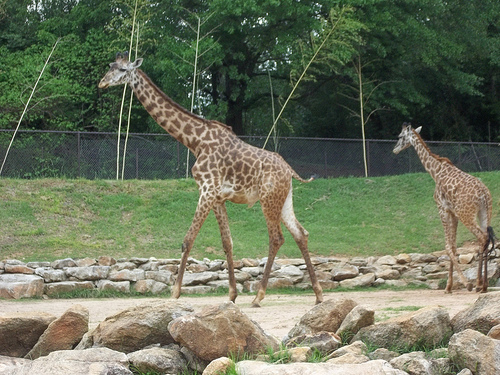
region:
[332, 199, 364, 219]
A slope covered in green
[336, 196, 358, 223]
Green grass on a slope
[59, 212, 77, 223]
A slope with dry grass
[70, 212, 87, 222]
Dry grass on a slope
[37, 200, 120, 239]
A slopy surface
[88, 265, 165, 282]
Stones arranged to make a wall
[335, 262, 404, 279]
A low wall of stones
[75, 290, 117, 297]
grass growing next to blocks of stone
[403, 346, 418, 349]
Growth of grass betwen rocks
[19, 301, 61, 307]
A path between rocks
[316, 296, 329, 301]
hoof of the giraffe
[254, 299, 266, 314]
hoof of the giraffe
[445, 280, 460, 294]
hoof of the giraffe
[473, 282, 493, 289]
hoof of the giraffe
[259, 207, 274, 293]
leg of the giraffe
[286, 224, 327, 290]
leg of the giraffe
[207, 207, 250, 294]
leg of the giraffe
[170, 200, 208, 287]
leg of the giraffe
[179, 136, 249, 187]
spots on the giraffe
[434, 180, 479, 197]
spots on the giraffe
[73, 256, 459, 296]
a low rock wall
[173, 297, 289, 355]
a large natural rock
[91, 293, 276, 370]
a pile of boulders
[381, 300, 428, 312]
a patch of grass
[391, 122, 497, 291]
a young giraffe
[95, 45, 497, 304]
a giraffe with it's baby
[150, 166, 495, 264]
a grass covered slope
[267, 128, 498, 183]
a metal chain link fence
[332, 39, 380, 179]
a tree with a thin trunk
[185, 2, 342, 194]
a tree in the background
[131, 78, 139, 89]
brown spot on giraffe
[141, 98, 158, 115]
brown spot on giraffe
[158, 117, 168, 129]
brown spot on giraffe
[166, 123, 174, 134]
brown spot on giraffe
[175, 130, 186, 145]
brown spot on giraffe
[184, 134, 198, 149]
brown spot on giraffe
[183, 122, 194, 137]
brown spot on giraffe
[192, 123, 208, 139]
brown spot on giraffe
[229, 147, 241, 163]
brown spot on giraffe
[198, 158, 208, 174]
brown spot on giraffe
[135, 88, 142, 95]
brown spot on giraffe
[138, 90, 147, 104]
brown spot on giraffe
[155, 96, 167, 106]
brown spot on giraffe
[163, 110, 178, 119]
brown spot on giraffe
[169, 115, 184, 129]
brown spot on giraffe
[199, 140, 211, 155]
brown spot on giraffe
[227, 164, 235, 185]
brown spot on giraffe